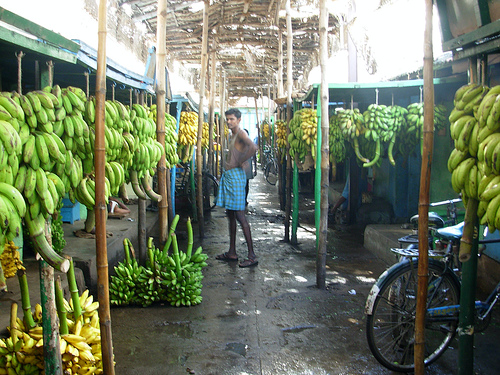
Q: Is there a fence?
A: No, there are no fences.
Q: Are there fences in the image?
A: No, there are no fences.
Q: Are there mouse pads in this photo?
A: No, there are no mouse pads.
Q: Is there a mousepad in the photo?
A: No, there are no mouse pads.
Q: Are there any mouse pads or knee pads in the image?
A: No, there are no mouse pads or knee pads.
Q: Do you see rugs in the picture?
A: No, there are no rugs.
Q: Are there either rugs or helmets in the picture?
A: No, there are no rugs or helmets.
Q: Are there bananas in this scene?
A: Yes, there is a banana.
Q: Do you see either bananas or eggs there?
A: Yes, there is a banana.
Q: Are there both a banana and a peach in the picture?
A: No, there is a banana but no peaches.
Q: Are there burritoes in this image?
A: No, there are no burritoes.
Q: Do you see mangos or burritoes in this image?
A: No, there are no burritoes or mangos.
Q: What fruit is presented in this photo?
A: The fruit is a banana.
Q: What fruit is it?
A: The fruit is a banana.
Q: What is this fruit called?
A: This is a banana.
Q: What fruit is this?
A: This is a banana.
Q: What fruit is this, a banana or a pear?
A: This is a banana.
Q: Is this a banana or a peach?
A: This is a banana.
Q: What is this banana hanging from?
A: The banana is hanging from the hook.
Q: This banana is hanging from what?
A: The banana is hanging from the hook.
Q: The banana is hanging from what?
A: The banana is hanging from the hook.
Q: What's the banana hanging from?
A: The banana is hanging from the hook.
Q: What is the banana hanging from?
A: The banana is hanging from the hook.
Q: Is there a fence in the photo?
A: No, there are no fences.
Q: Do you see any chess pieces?
A: No, there are no chess pieces.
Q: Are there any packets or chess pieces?
A: No, there are no chess pieces or packets.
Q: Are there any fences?
A: No, there are no fences.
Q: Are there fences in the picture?
A: No, there are no fences.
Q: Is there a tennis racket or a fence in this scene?
A: No, there are no fences or rackets.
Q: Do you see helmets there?
A: No, there are no helmets.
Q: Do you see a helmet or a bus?
A: No, there are no helmets or buses.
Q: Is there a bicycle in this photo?
A: Yes, there is a bicycle.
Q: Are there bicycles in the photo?
A: Yes, there is a bicycle.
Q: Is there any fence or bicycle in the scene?
A: Yes, there is a bicycle.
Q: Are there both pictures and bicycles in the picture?
A: No, there is a bicycle but no pictures.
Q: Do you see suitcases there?
A: No, there are no suitcases.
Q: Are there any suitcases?
A: No, there are no suitcases.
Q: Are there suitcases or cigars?
A: No, there are no suitcases or cigars.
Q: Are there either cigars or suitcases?
A: No, there are no suitcases or cigars.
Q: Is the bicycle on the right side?
A: Yes, the bicycle is on the right of the image.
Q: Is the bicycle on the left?
A: No, the bicycle is on the right of the image.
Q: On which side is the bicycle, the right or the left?
A: The bicycle is on the right of the image.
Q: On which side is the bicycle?
A: The bicycle is on the right of the image.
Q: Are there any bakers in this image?
A: No, there are no bakers.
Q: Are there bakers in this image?
A: No, there are no bakers.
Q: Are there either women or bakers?
A: No, there are no bakers or women.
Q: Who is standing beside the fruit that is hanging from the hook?
A: The man is standing beside the banana.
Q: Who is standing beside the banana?
A: The man is standing beside the banana.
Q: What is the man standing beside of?
A: The man is standing beside the banana.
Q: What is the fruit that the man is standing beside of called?
A: The fruit is a banana.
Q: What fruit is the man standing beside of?
A: The man is standing beside the banana.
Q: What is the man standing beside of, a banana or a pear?
A: The man is standing beside a banana.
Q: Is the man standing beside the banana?
A: Yes, the man is standing beside the banana.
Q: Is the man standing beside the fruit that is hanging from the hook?
A: Yes, the man is standing beside the banana.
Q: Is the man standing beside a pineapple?
A: No, the man is standing beside the banana.